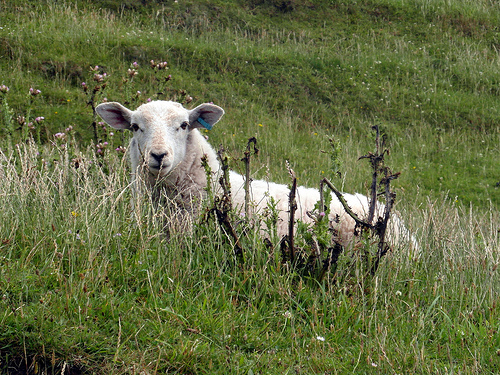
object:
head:
[92, 98, 227, 177]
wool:
[148, 106, 168, 135]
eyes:
[130, 121, 144, 133]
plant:
[80, 59, 194, 166]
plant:
[321, 121, 405, 299]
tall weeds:
[0, 133, 500, 373]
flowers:
[92, 64, 102, 71]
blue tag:
[196, 117, 214, 132]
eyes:
[179, 120, 190, 132]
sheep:
[84, 92, 423, 259]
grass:
[0, 0, 500, 302]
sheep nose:
[151, 148, 172, 164]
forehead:
[137, 101, 179, 122]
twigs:
[322, 179, 374, 230]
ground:
[1, 0, 500, 374]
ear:
[189, 101, 227, 130]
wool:
[260, 183, 274, 192]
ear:
[93, 101, 131, 130]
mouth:
[146, 160, 172, 172]